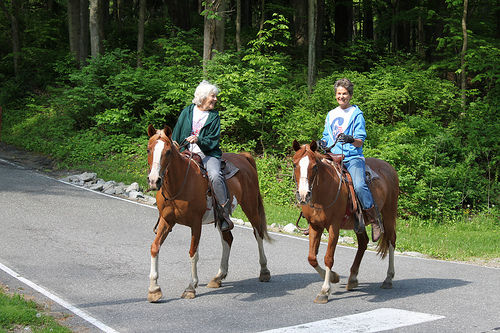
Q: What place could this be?
A: It is a forest.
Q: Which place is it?
A: It is a forest.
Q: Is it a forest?
A: Yes, it is a forest.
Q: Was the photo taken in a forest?
A: Yes, it was taken in a forest.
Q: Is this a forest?
A: Yes, it is a forest.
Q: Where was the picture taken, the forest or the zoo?
A: It was taken at the forest.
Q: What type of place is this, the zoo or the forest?
A: It is the forest.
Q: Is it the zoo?
A: No, it is the forest.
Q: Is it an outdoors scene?
A: Yes, it is outdoors.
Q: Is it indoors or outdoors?
A: It is outdoors.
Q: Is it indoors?
A: No, it is outdoors.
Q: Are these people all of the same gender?
A: Yes, all the people are female.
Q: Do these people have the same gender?
A: Yes, all the people are female.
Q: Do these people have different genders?
A: No, all the people are female.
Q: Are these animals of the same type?
A: Yes, all the animals are horses.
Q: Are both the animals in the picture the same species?
A: Yes, all the animals are horses.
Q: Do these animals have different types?
A: No, all the animals are horses.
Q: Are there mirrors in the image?
A: No, there are no mirrors.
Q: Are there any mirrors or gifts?
A: No, there are no mirrors or gifts.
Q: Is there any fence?
A: No, there are no fences.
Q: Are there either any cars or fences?
A: No, there are no fences or cars.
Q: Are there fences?
A: No, there are no fences.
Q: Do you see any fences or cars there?
A: No, there are no fences or cars.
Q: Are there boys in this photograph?
A: No, there are no boys.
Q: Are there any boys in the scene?
A: No, there are no boys.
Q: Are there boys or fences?
A: No, there are no boys or fences.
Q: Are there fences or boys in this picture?
A: No, there are no boys or fences.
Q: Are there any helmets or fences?
A: No, there are no fences or helmets.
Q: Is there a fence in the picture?
A: No, there are no fences.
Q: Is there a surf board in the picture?
A: No, there are no surfboards.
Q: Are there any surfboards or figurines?
A: No, there are no surfboards or figurines.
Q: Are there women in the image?
A: Yes, there is a woman.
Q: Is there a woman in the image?
A: Yes, there is a woman.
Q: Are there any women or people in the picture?
A: Yes, there is a woman.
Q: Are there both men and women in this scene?
A: No, there is a woman but no men.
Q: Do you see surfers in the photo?
A: No, there are no surfers.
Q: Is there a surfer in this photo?
A: No, there are no surfers.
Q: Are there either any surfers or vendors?
A: No, there are no surfers or vendors.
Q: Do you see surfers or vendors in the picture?
A: No, there are no surfers or vendors.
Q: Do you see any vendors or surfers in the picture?
A: No, there are no surfers or vendors.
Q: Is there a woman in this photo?
A: Yes, there is a woman.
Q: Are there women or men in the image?
A: Yes, there is a woman.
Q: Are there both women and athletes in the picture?
A: No, there is a woman but no athletes.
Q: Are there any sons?
A: No, there are no sons.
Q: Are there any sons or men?
A: No, there are no sons or men.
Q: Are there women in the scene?
A: Yes, there is a woman.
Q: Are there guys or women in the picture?
A: Yes, there is a woman.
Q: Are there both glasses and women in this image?
A: No, there is a woman but no glasses.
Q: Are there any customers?
A: No, there are no customers.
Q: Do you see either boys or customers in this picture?
A: No, there are no customers or boys.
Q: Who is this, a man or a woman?
A: This is a woman.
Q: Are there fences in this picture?
A: No, there are no fences.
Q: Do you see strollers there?
A: No, there are no strollers.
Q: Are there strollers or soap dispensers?
A: No, there are no strollers or soap dispensers.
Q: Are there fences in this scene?
A: No, there are no fences.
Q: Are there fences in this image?
A: No, there are no fences.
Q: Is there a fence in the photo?
A: No, there are no fences.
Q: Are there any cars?
A: No, there are no cars.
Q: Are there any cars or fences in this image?
A: No, there are no cars or fences.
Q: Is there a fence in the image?
A: No, there are no fences.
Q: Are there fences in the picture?
A: No, there are no fences.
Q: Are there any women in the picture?
A: Yes, there is a woman.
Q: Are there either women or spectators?
A: Yes, there is a woman.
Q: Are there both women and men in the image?
A: No, there is a woman but no men.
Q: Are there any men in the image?
A: No, there are no men.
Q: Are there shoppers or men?
A: No, there are no men or shoppers.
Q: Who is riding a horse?
A: The woman is riding a horse.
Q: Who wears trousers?
A: The woman wears trousers.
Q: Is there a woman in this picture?
A: Yes, there is a woman.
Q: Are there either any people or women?
A: Yes, there is a woman.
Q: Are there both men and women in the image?
A: No, there is a woman but no men.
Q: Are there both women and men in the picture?
A: No, there is a woman but no men.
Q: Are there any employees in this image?
A: No, there are no employees.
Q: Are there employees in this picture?
A: No, there are no employees.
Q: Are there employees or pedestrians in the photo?
A: No, there are no employees or pedestrians.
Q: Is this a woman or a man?
A: This is a woman.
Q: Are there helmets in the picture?
A: No, there are no helmets.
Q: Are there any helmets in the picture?
A: No, there are no helmets.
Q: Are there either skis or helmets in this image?
A: No, there are no helmets or skis.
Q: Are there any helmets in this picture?
A: No, there are no helmets.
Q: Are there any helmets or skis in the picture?
A: No, there are no helmets or skis.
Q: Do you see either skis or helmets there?
A: No, there are no helmets or skis.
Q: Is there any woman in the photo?
A: Yes, there is a woman.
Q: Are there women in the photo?
A: Yes, there is a woman.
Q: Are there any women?
A: Yes, there is a woman.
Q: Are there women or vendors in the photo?
A: Yes, there is a woman.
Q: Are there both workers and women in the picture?
A: No, there is a woman but no workers.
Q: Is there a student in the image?
A: No, there are no students.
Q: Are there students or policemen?
A: No, there are no students or policemen.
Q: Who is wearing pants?
A: The woman is wearing pants.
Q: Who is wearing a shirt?
A: The woman is wearing a shirt.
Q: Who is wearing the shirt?
A: The woman is wearing a shirt.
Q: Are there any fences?
A: No, there are no fences.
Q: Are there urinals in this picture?
A: No, there are no urinals.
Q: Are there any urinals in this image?
A: No, there are no urinals.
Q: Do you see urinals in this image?
A: No, there are no urinals.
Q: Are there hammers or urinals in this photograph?
A: No, there are no urinals or hammers.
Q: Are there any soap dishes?
A: No, there are no soap dishes.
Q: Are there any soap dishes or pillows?
A: No, there are no soap dishes or pillows.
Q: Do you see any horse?
A: Yes, there is a horse.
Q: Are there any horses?
A: Yes, there is a horse.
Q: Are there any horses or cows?
A: Yes, there is a horse.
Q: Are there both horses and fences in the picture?
A: No, there is a horse but no fences.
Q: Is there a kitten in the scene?
A: No, there are no kittens.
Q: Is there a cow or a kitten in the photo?
A: No, there are no kittens or cows.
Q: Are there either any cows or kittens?
A: No, there are no kittens or cows.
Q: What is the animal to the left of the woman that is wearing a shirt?
A: The animal is a horse.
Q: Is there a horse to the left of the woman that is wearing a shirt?
A: Yes, there is a horse to the left of the woman.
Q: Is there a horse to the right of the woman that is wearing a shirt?
A: No, the horse is to the left of the woman.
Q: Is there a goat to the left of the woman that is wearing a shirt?
A: No, there is a horse to the left of the woman.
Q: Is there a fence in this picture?
A: No, there are no fences.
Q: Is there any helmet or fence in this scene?
A: No, there are no fences or helmets.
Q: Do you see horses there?
A: Yes, there is a horse.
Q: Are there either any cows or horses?
A: Yes, there is a horse.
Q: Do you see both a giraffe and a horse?
A: No, there is a horse but no giraffes.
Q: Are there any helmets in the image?
A: No, there are no helmets.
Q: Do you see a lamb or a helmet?
A: No, there are no helmets or lambs.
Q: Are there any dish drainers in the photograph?
A: No, there are no dish drainers.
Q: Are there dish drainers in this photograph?
A: No, there are no dish drainers.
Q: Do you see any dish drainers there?
A: No, there are no dish drainers.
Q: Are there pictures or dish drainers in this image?
A: No, there are no dish drainers or pictures.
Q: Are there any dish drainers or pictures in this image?
A: No, there are no dish drainers or pictures.